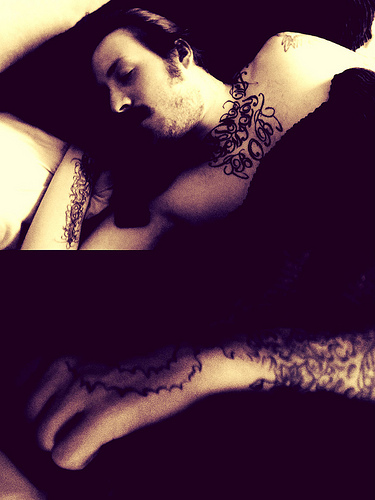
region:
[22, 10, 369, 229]
tattooed man sleeping in bed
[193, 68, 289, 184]
tattoo on man's chest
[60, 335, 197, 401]
tattoo on top of man's hand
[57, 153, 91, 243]
tattoo on man's wrist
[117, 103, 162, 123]
dark mustacke of man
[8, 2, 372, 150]
black pillow man is sleeping on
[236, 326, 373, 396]
tattoos on man's arm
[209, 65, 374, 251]
black blanket covering man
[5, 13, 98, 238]
white pillows beside man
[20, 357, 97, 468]
fingers of tattooed man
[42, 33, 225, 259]
A guy sleeping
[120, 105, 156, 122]
Mustache on the man sleeping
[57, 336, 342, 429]
Closeup of the man's arm above the blanket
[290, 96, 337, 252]
Blanket on a man sleeping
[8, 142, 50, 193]
White sheets below man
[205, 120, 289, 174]
Chest piece tattoo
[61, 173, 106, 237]
Tribal artwork on inner forearm tattoo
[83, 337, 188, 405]
Tattoo on top of the hand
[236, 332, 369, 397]
Sleeve style tribal work on outer forarm tattoo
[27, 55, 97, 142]
A black pillow below the man's head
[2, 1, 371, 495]
tattoo'd man is sleeping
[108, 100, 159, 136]
man has a thick mustache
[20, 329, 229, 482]
man's hand is on the bedcovers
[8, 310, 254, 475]
man's hand is tattoo'd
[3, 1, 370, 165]
man's head is on a dark pillow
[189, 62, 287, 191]
mans chest is tattoo'd with letters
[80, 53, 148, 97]
mans eyes are closed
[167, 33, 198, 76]
mans left ear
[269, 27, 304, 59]
shoulder is tattoo'd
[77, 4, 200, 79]
man has thick dark hair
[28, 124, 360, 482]
picture taken indoors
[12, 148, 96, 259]
sunlight on the man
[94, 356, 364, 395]
the man has tattoos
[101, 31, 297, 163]
The man is sleeping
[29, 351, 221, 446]
The man has tattoos on his hand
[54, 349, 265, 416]
The tattoos are outlined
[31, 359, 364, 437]
A close up of his left hand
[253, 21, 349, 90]
The man's left shoulder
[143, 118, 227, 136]
The man has a slight beard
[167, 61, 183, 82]
The man has a side burn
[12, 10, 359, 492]
2 pictures of a tattoed man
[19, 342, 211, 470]
tattoed man hand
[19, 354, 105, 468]
3 0f 5 fingers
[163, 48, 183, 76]
black side burn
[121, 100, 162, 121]
mans black moustache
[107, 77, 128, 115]
nose of tattoed man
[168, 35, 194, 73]
ear of tattoed man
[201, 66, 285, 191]
chest tattoo of man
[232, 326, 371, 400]
arm tattoo of man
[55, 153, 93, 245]
tattoo on fore arm of man